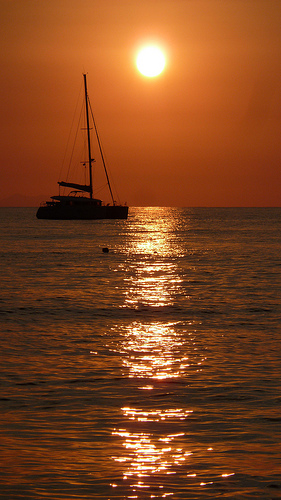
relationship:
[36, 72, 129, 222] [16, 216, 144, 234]
boat sailing in water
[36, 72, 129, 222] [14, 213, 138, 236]
boat sitting in ocean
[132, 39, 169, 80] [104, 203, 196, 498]
sun has reflection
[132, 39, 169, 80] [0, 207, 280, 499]
sun on water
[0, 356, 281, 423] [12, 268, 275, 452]
ripples on water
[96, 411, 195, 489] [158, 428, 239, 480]
sun reflected on water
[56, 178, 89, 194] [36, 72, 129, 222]
sails on boat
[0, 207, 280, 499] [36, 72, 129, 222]
water by boat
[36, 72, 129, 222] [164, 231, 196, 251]
boat on water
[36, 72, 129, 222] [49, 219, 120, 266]
boat on water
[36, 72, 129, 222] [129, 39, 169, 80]
boat under sun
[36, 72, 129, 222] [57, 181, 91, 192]
boat has sails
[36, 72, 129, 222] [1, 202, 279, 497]
boat on sea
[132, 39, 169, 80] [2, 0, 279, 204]
sun in sky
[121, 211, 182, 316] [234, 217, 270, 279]
reflection on water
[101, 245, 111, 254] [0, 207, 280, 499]
object on water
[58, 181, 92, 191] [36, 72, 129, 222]
sail on boat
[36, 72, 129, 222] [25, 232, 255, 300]
boat on water